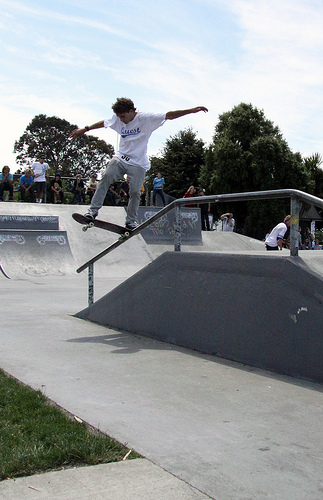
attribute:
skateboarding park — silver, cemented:
[2, 207, 288, 499]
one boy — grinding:
[60, 84, 227, 230]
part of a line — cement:
[152, 255, 293, 292]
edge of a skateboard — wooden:
[59, 206, 85, 231]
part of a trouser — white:
[92, 156, 130, 214]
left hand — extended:
[142, 100, 217, 129]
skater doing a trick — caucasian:
[29, 74, 211, 234]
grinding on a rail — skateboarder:
[37, 170, 321, 263]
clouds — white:
[236, 2, 313, 46]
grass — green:
[0, 398, 56, 474]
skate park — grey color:
[1, 203, 311, 434]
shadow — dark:
[68, 330, 187, 355]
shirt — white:
[103, 113, 164, 169]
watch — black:
[82, 124, 90, 133]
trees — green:
[207, 101, 312, 190]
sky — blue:
[1, 1, 310, 95]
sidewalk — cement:
[142, 369, 311, 498]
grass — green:
[0, 392, 56, 470]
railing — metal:
[172, 186, 300, 208]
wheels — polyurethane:
[82, 221, 96, 230]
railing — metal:
[171, 188, 304, 249]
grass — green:
[0, 385, 31, 471]